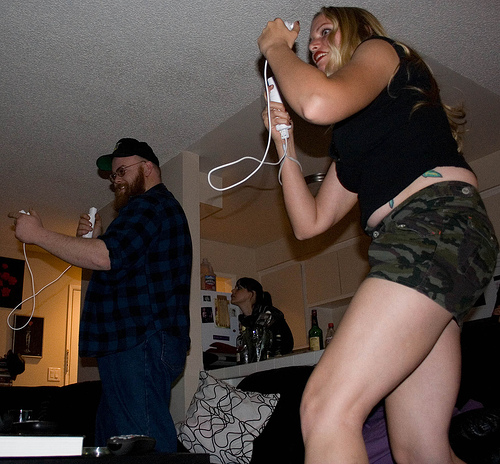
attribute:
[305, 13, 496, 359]
woman — standing, playing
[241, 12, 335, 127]
controllers — wii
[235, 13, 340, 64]
hands — holding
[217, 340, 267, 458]
pillow — black, brown, here, throw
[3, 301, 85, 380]
picture — framed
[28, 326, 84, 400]
switch — white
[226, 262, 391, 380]
kitchen — behind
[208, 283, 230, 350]
refrigerator — white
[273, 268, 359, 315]
cabinets — beige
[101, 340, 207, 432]
jeans — blue, here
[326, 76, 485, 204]
shirt — black, here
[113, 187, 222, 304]
shirt — plaid, blue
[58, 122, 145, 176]
cap — baseball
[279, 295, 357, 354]
bottle — sitting, here, glass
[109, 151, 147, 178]
man — playing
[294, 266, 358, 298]
drawer — here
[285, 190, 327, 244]
elbow — here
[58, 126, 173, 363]
person — standing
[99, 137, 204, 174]
hat — black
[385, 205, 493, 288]
shorts — camo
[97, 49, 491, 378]
people — playing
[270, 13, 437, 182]
girl — young